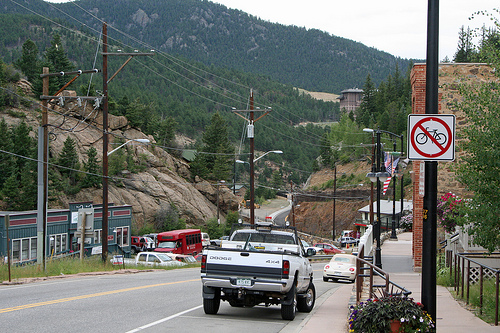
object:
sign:
[407, 114, 456, 161]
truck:
[199, 219, 317, 321]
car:
[321, 252, 358, 282]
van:
[201, 233, 211, 249]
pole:
[248, 87, 255, 229]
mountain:
[0, 0, 408, 88]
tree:
[189, 109, 235, 184]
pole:
[417, 0, 440, 333]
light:
[375, 126, 382, 135]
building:
[0, 200, 132, 268]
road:
[0, 265, 339, 333]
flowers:
[346, 294, 436, 332]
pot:
[387, 319, 402, 333]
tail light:
[283, 260, 290, 275]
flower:
[365, 299, 373, 305]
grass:
[1, 257, 117, 279]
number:
[266, 260, 280, 265]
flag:
[383, 158, 400, 196]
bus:
[154, 229, 203, 256]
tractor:
[240, 199, 261, 209]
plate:
[236, 279, 251, 286]